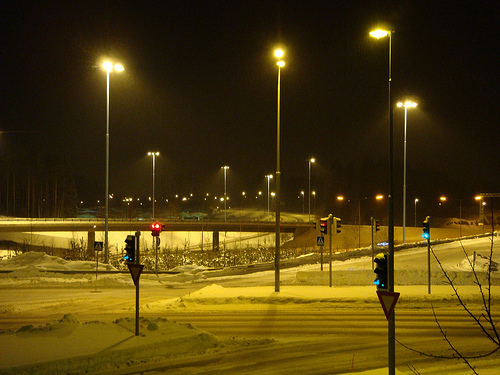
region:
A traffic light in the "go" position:
[118, 230, 141, 268]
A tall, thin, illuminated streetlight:
[269, 35, 289, 295]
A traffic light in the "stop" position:
[150, 223, 165, 238]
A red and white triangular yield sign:
[374, 287, 403, 319]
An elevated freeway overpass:
[164, 216, 272, 251]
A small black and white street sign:
[86, 235, 108, 289]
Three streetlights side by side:
[142, 146, 275, 215]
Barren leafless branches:
[439, 235, 497, 364]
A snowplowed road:
[175, 297, 357, 354]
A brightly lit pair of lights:
[93, 55, 137, 74]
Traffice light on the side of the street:
[122, 229, 144, 343]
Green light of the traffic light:
[122, 253, 132, 260]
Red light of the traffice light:
[149, 222, 161, 230]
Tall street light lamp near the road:
[96, 56, 125, 264]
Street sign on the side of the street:
[91, 240, 103, 277]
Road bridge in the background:
[1, 216, 315, 236]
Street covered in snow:
[144, 283, 499, 309]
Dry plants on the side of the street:
[57, 236, 322, 269]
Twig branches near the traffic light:
[395, 213, 499, 372]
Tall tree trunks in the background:
[0, 165, 85, 217]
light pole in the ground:
[148, 146, 166, 215]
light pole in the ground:
[217, 157, 238, 222]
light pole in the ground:
[99, 45, 134, 231]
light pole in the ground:
[264, 35, 294, 217]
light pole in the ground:
[363, 8, 403, 210]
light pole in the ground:
[395, 80, 421, 237]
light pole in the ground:
[333, 188, 365, 258]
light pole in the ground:
[262, 173, 276, 217]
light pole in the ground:
[243, 190, 253, 229]